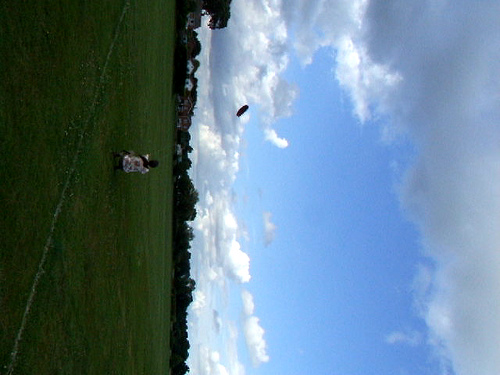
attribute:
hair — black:
[147, 156, 165, 176]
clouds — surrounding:
[371, 10, 493, 292]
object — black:
[235, 94, 257, 121]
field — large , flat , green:
[2, 2, 192, 369]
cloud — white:
[216, 234, 252, 283]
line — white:
[51, 67, 158, 161]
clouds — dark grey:
[348, 4, 499, 368]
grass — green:
[1, 56, 161, 371]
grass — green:
[82, 273, 163, 354]